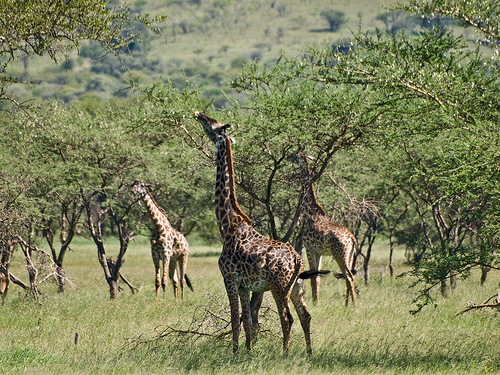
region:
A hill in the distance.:
[5, 2, 499, 85]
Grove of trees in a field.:
[2, 0, 496, 305]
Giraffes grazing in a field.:
[125, 108, 367, 355]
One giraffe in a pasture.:
[208, 123, 323, 367]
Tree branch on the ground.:
[132, 293, 284, 365]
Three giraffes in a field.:
[128, 110, 368, 370]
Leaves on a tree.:
[1, 0, 170, 73]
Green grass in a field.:
[0, 245, 495, 374]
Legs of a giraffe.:
[222, 278, 313, 363]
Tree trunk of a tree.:
[83, 219, 140, 301]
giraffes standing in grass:
[103, 87, 375, 362]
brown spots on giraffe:
[235, 243, 260, 270]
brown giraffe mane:
[223, 134, 258, 229]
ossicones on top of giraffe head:
[214, 117, 233, 132]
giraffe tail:
[278, 250, 333, 313]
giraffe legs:
[229, 303, 321, 365]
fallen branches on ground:
[114, 290, 294, 366]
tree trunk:
[103, 278, 120, 304]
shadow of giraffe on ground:
[198, 323, 498, 373]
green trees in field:
[8, 92, 175, 315]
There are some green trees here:
[424, 158, 443, 228]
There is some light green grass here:
[360, 303, 375, 352]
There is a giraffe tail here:
[279, 296, 292, 350]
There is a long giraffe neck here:
[213, 162, 246, 221]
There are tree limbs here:
[173, 321, 180, 337]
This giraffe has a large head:
[132, 167, 153, 204]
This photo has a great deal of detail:
[153, 191, 278, 368]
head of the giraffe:
[182, 110, 233, 150]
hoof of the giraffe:
[280, 347, 295, 358]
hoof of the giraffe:
[240, 336, 253, 357]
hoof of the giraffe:
[223, 329, 240, 349]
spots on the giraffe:
[241, 243, 264, 260]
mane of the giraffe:
[222, 157, 254, 225]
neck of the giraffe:
[217, 145, 243, 215]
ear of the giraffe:
[218, 118, 230, 136]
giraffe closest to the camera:
[191, 107, 316, 364]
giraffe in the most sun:
[129, 178, 198, 298]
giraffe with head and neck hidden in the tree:
[295, 139, 368, 306]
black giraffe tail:
[295, 267, 334, 282]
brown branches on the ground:
[131, 292, 289, 356]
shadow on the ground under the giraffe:
[170, 327, 485, 367]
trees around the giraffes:
[2, 0, 497, 310]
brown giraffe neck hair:
[223, 130, 256, 227]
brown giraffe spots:
[230, 237, 289, 280]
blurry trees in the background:
[6, 0, 488, 100]